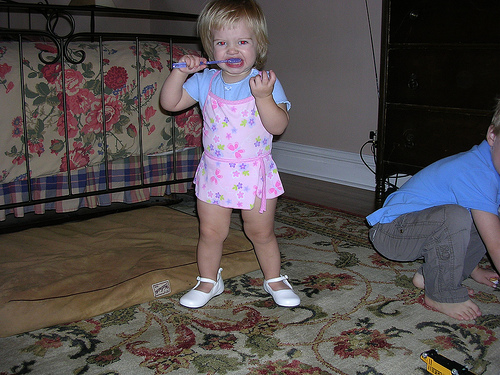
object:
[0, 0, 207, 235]
frame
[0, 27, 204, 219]
bed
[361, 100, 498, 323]
boy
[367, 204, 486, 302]
pants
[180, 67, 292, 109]
shirt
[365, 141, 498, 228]
shirt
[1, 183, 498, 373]
carpet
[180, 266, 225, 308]
shoe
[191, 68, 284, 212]
dress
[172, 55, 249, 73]
brushing teeth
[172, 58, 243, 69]
toothbrush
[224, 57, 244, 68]
mouth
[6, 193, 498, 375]
area rug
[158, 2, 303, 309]
child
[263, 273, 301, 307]
shoes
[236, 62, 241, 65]
teeth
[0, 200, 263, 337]
mat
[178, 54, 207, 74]
hand